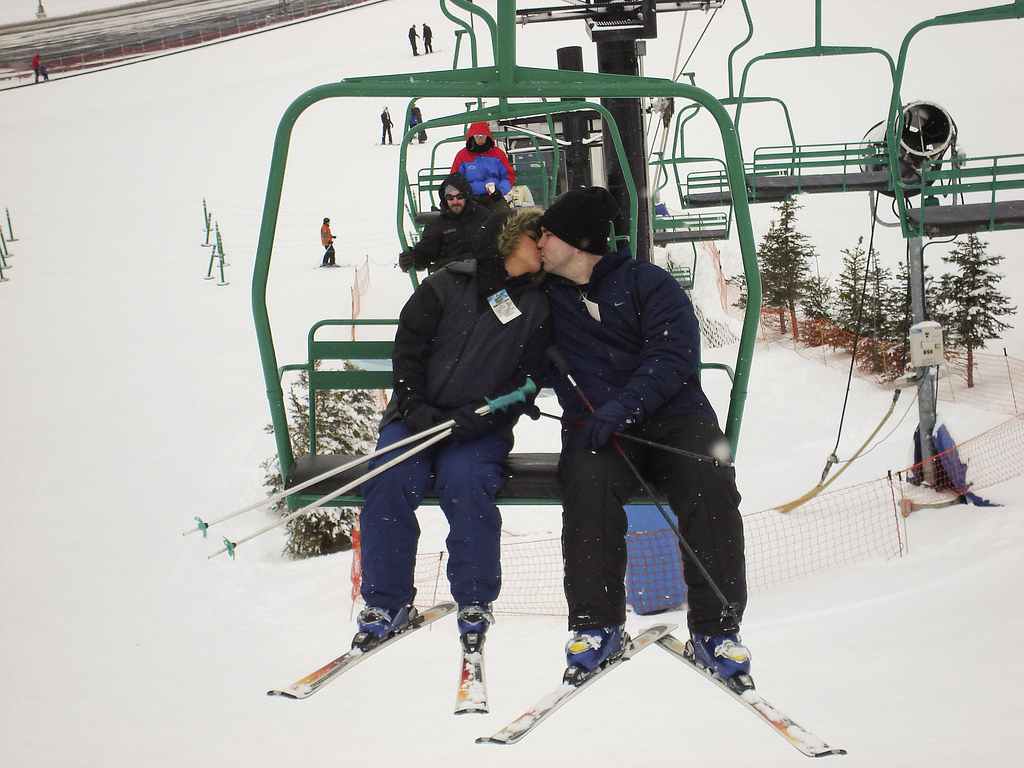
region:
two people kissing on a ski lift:
[248, 1, 762, 694]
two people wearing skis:
[263, 186, 851, 756]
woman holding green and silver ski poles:
[184, 203, 543, 650]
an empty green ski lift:
[732, 0, 898, 196]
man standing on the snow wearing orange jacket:
[315, 214, 336, 268]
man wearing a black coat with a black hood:
[400, 172, 496, 275]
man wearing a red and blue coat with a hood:
[450, 121, 515, 195]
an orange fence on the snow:
[349, 220, 1020, 620]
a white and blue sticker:
[485, 287, 518, 323]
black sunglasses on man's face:
[438, 172, 471, 217]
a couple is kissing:
[363, 183, 730, 441]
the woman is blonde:
[468, 201, 554, 328]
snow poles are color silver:
[129, 375, 550, 575]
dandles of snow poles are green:
[477, 371, 548, 425]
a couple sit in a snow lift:
[236, 68, 786, 729]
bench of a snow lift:
[866, 15, 1022, 244]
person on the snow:
[297, 204, 352, 275]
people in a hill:
[326, 3, 459, 147]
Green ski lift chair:
[251, 62, 767, 515]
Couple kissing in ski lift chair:
[257, 185, 847, 767]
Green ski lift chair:
[889, 2, 1023, 236]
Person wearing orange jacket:
[315, 216, 338, 274]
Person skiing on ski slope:
[377, 102, 398, 147]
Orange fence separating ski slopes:
[750, 416, 1023, 571]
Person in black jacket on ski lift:
[399, 175, 505, 273]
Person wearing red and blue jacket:
[453, 116, 518, 199]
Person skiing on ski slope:
[24, 46, 51, 86]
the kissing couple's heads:
[488, 199, 616, 294]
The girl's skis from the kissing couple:
[261, 554, 518, 726]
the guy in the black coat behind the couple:
[415, 179, 515, 277]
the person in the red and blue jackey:
[431, 104, 539, 204]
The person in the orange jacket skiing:
[294, 205, 372, 295]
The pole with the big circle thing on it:
[858, 91, 989, 528]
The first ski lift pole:
[571, 6, 679, 263]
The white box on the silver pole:
[906, 322, 946, 376]